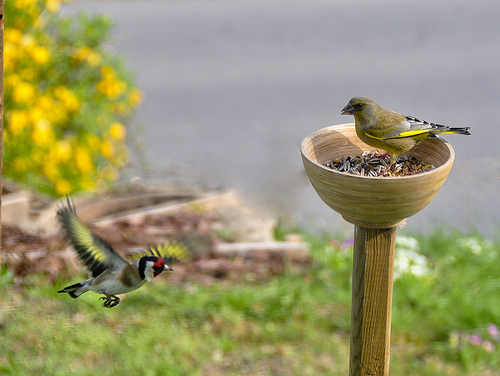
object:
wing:
[362, 124, 432, 144]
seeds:
[339, 158, 351, 171]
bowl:
[297, 121, 453, 230]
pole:
[349, 227, 397, 375]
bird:
[54, 193, 214, 308]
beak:
[153, 255, 180, 272]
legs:
[383, 156, 397, 169]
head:
[141, 254, 172, 277]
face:
[151, 257, 168, 278]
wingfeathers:
[55, 193, 130, 277]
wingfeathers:
[129, 232, 219, 264]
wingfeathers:
[375, 113, 435, 140]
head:
[337, 95, 365, 117]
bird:
[336, 95, 474, 183]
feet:
[375, 162, 392, 173]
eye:
[352, 100, 364, 111]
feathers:
[366, 116, 421, 141]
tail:
[436, 125, 473, 137]